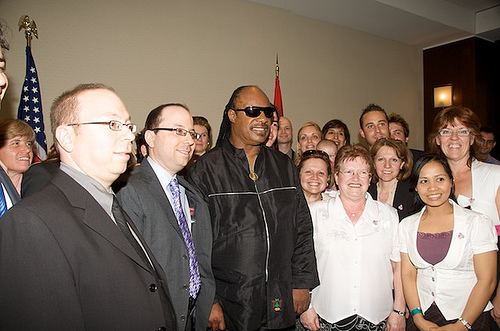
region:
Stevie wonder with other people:
[186, 73, 324, 329]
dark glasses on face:
[238, 99, 286, 122]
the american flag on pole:
[18, 34, 62, 181]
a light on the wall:
[421, 62, 458, 109]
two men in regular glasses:
[53, 96, 203, 168]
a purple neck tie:
[171, 180, 214, 307]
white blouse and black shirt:
[298, 188, 408, 328]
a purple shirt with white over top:
[394, 207, 499, 325]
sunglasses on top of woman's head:
[295, 143, 333, 161]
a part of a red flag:
[270, 74, 303, 153]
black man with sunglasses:
[192, 83, 314, 329]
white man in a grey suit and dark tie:
[0, 90, 175, 330]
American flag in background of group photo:
[10, 12, 62, 160]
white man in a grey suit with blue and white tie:
[113, 99, 221, 328]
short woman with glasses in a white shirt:
[290, 150, 404, 330]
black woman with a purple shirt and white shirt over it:
[395, 157, 495, 329]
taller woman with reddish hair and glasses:
[423, 105, 487, 167]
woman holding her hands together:
[391, 154, 491, 329]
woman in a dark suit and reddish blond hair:
[362, 135, 410, 190]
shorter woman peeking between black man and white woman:
[291, 143, 334, 198]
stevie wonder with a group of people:
[213, 76, 308, 329]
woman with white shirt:
[406, 153, 498, 329]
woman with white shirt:
[333, 150, 381, 330]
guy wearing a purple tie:
[135, 90, 215, 328]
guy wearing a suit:
[32, 72, 145, 328]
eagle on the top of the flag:
[12, 10, 47, 50]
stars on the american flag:
[20, 30, 47, 127]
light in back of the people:
[415, 76, 460, 106]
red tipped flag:
[272, 55, 287, 102]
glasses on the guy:
[77, 115, 139, 131]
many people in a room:
[20, 55, 485, 253]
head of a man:
[211, 68, 294, 160]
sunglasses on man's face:
[226, 90, 288, 130]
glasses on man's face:
[90, 103, 145, 148]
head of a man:
[153, 100, 206, 165]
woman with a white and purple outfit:
[388, 162, 478, 269]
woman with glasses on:
[314, 146, 386, 221]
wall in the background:
[108, 16, 202, 68]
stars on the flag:
[13, 65, 55, 120]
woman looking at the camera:
[428, 108, 478, 158]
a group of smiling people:
[0, 82, 497, 329]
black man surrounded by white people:
[3, 82, 499, 329]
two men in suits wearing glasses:
[2, 80, 214, 330]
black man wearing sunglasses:
[191, 84, 321, 329]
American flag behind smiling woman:
[2, 14, 49, 189]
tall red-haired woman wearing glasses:
[425, 102, 496, 223]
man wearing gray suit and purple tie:
[115, 102, 216, 327]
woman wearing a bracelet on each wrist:
[396, 151, 496, 327]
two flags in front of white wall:
[0, 0, 421, 156]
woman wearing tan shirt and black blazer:
[368, 135, 419, 216]